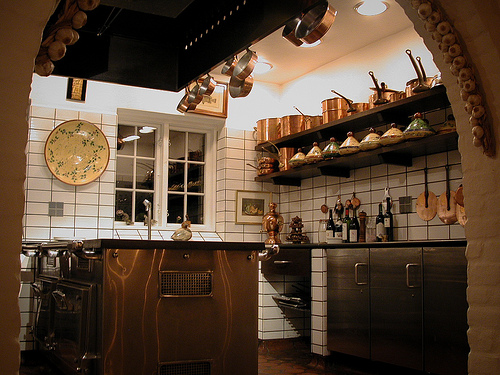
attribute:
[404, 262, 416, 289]
handle — metal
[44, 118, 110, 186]
plate — decorative, yellow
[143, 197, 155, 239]
faucet — tall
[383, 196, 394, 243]
bottle — wine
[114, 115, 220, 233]
window — closed, reflecting, rectangular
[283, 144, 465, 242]
back splash — gray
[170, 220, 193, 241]
knick knack — ceramic, quail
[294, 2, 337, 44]
pan — copper, hanging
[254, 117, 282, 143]
pot — copper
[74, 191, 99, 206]
tile — white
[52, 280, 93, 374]
oven — metal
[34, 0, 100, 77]
garlic — bundle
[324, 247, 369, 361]
cupboard — stainless steel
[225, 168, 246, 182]
tile — white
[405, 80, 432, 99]
frying pan — copper coated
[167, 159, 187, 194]
pane — glass